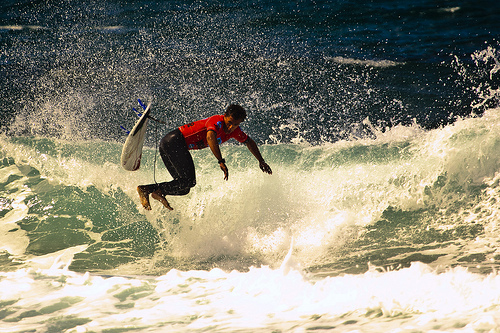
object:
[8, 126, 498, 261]
wave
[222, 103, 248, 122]
hair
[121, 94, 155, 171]
board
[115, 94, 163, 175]
surfboard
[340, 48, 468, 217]
sheep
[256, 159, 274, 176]
left hand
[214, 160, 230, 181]
hand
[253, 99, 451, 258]
foam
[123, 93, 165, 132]
fin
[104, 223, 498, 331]
foam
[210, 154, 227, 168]
watch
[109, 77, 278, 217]
surfer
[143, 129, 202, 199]
wetsuit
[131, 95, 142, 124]
handles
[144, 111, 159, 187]
cord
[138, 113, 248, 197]
water suit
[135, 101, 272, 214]
man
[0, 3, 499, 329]
water